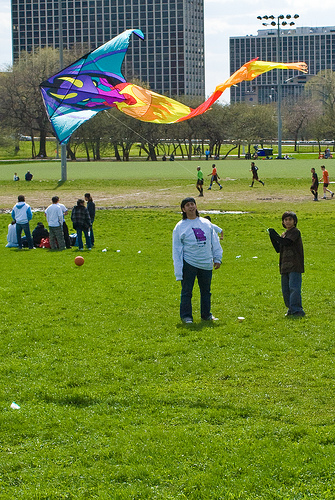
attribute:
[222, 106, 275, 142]
buds — light green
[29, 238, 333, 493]
grass — green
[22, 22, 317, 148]
colored kite — long, multi colored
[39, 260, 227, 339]
grass in park — green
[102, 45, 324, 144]
yellow kite flying — purple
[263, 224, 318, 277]
sleeve sweater — long sleeve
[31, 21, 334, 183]
kite flying — colorful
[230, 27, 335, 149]
office building — tall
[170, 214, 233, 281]
white hoodie — blue